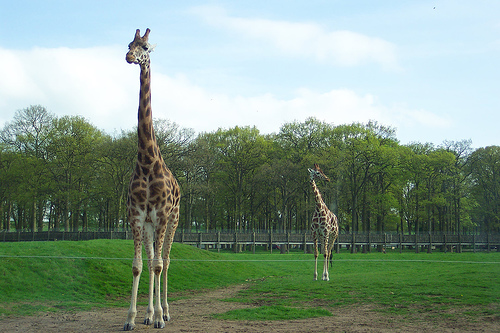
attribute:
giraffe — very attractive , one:
[301, 160, 336, 283]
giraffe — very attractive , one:
[126, 26, 181, 331]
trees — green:
[341, 164, 477, 246]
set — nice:
[367, 180, 453, 250]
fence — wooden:
[6, 222, 483, 264]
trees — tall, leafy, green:
[186, 122, 303, 251]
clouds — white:
[2, 47, 281, 141]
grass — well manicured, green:
[356, 249, 484, 319]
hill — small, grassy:
[1, 234, 251, 304]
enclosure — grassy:
[2, 237, 482, 329]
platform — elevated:
[182, 231, 478, 257]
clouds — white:
[13, 41, 383, 130]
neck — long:
[309, 173, 330, 218]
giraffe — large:
[123, 22, 183, 329]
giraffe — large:
[297, 163, 340, 281]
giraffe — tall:
[299, 160, 340, 286]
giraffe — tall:
[118, 20, 185, 330]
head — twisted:
[306, 163, 332, 184]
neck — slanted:
[310, 177, 324, 204]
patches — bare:
[0, 283, 497, 331]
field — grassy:
[2, 239, 496, 330]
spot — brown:
[148, 159, 164, 179]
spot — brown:
[145, 172, 155, 182]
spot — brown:
[138, 167, 151, 177]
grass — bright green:
[0, 237, 235, 308]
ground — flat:
[199, 252, 495, 331]